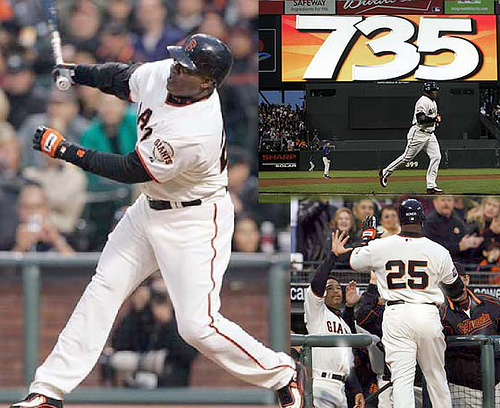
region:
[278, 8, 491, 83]
number on a score board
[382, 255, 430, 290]
number on the man's shirt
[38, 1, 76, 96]
bat in a man's hand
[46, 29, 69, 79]
tape on a bat handle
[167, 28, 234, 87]
helmet on a batter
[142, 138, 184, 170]
team name on the shoulder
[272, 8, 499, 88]
Number 735 stands out bright background.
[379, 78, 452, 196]
Baseball player runs on field.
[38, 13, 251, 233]
Powerful swing player at bat.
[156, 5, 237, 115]
Black safety helmet protection.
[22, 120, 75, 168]
Black and orange batting glove.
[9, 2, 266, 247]
Spectator fans blurry picture.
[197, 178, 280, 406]
Red stripe along white uniform pants.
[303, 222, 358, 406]
Play in dugout reaches hand high.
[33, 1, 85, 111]
Player baseball bat right hand.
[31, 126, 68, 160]
Black and orange glove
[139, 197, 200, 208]
Belt around man's waist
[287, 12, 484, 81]
White numbers on a sign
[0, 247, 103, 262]
Gray post on fence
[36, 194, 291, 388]
White pants on player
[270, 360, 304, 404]
Shoe on a baseball player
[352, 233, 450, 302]
Baseball jersey on a man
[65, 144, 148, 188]
Black sleeve on baseball player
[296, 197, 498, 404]
Batter is high fiving team mates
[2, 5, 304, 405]
Player has hit the ball in the field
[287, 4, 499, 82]
The number indicates the home runs the player has hit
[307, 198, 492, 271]
The crowd is clapping in the stands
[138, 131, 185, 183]
Logo is on the arm of the jersey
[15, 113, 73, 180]
Player is wearing multicolored gloves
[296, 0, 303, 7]
black letter on sign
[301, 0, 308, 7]
black letter on sign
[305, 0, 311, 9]
black letter on sign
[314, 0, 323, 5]
black letter on sign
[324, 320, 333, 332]
black letter on jersey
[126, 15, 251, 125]
head of a player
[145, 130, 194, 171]
logo on the jersey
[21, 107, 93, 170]
glove of the batter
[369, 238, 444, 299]
number on the jersey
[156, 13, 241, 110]
the man has black hat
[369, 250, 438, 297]
the number is 25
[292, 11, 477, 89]
the number is 735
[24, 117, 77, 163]
the glove has orange on it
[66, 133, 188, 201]
a long black sleeve shirt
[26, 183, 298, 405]
white pants with red stripe on the side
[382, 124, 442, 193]
white pants with red stripe on the side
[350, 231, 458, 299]
white shirt with black numbers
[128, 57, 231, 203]
white shirt with black letters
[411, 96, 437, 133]
white shirt with black letters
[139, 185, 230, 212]
cinched black leather belt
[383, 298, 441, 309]
cinched black leather belt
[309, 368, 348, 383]
cinched black leather belt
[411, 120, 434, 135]
cinched black leather belt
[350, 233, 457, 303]
white baseball shirt with black numbers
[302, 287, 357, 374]
white baseball shirt with black letters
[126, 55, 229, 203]
white baseball shirt with black letters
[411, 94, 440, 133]
white baseball shirt with black letters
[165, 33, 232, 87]
black baseball helmet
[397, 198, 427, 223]
black baseball helmet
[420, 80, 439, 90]
black baseball helmet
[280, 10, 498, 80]
red and yellow sign with white letters